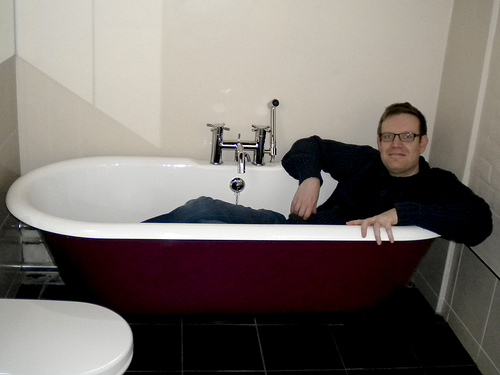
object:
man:
[137, 100, 492, 247]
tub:
[1, 154, 441, 316]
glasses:
[376, 132, 427, 143]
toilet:
[0, 296, 132, 375]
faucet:
[205, 121, 270, 179]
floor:
[0, 269, 482, 375]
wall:
[0, 0, 454, 176]